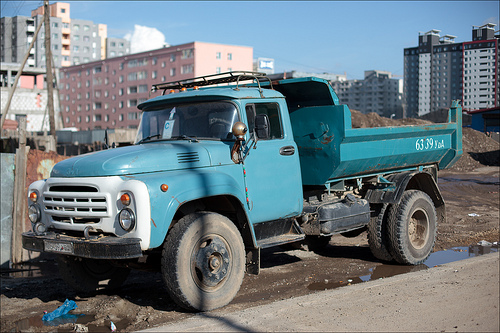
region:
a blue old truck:
[48, 54, 472, 330]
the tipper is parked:
[11, 63, 496, 296]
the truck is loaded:
[6, 50, 498, 304]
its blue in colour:
[0, 64, 498, 301]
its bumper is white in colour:
[2, 130, 240, 317]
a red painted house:
[67, 55, 139, 129]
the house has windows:
[51, 66, 136, 127]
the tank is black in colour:
[303, 196, 375, 239]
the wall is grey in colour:
[404, 38, 498, 105]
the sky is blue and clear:
[249, 9, 402, 54]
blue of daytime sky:
[68, 1, 497, 74]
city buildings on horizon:
[0, 0, 499, 106]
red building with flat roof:
[60, 40, 255, 131]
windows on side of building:
[57, 42, 196, 128]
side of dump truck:
[29, 68, 461, 311]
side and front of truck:
[28, 72, 465, 310]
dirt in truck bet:
[297, 75, 459, 182]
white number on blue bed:
[341, 103, 464, 170]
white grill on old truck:
[25, 174, 149, 244]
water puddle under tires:
[340, 193, 495, 288]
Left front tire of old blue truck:
[158, 207, 255, 317]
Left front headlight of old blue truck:
[112, 205, 142, 234]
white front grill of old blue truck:
[12, 179, 153, 232]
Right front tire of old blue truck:
[23, 203, 43, 224]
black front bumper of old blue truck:
[14, 226, 147, 265]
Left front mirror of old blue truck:
[227, 120, 254, 163]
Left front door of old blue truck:
[230, 94, 310, 230]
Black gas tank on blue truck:
[302, 186, 376, 245]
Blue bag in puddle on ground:
[28, 293, 98, 331]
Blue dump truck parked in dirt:
[21, 57, 474, 318]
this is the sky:
[270, 7, 385, 54]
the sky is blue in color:
[323, 5, 361, 30]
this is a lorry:
[107, 72, 387, 270]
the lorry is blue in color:
[237, 167, 292, 202]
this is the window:
[252, 106, 288, 128]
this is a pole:
[37, 4, 62, 127]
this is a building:
[419, 30, 499, 104]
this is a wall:
[189, 42, 214, 72]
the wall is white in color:
[471, 63, 490, 95]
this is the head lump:
[112, 195, 141, 229]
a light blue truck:
[21, 71, 470, 303]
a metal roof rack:
[144, 68, 269, 94]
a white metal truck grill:
[19, 175, 152, 260]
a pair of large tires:
[365, 185, 437, 268]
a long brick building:
[54, 41, 258, 148]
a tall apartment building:
[396, 22, 496, 120]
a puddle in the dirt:
[313, 230, 497, 286]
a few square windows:
[68, 20, 96, 61]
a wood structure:
[25, 9, 59, 135]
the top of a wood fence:
[48, 138, 107, 155]